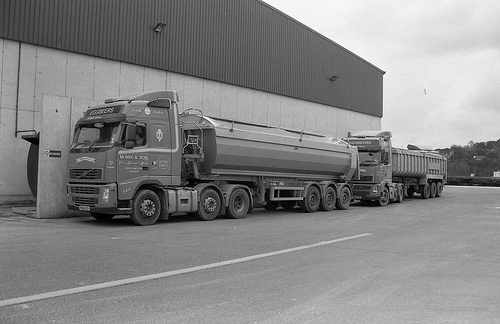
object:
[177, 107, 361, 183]
tanker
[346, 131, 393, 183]
cab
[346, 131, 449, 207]
dump truck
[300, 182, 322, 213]
wheel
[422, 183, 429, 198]
wheel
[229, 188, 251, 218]
wheel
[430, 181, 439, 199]
wheel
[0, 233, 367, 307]
line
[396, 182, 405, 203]
rubber wheel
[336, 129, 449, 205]
truck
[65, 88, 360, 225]
truck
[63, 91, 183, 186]
cab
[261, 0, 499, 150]
sky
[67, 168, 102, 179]
vents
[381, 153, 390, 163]
mirror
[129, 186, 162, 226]
wheel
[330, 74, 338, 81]
light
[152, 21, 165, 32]
light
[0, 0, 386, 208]
building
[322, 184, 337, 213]
wheel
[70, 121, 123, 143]
windshield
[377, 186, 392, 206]
wheel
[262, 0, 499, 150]
cloud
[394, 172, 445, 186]
bed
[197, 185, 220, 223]
wheel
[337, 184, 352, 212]
wheel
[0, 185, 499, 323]
road